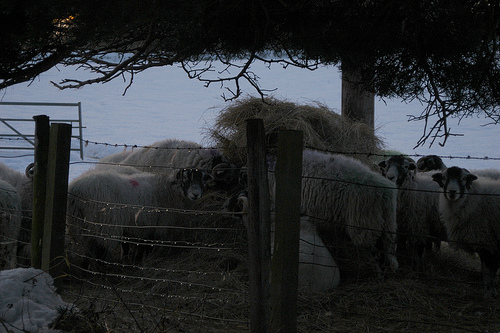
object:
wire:
[304, 143, 500, 163]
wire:
[300, 172, 500, 198]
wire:
[72, 190, 240, 219]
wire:
[74, 256, 249, 279]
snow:
[0, 52, 500, 182]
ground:
[2, 54, 500, 332]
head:
[375, 153, 420, 190]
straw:
[206, 94, 384, 168]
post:
[337, 47, 377, 137]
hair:
[258, 128, 290, 165]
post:
[244, 116, 275, 332]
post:
[265, 127, 303, 332]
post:
[28, 112, 50, 269]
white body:
[68, 171, 176, 258]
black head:
[167, 165, 213, 202]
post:
[41, 121, 75, 278]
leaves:
[483, 1, 498, 12]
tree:
[0, 0, 498, 155]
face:
[181, 168, 208, 200]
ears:
[428, 172, 447, 185]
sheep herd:
[1, 138, 498, 332]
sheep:
[1, 178, 26, 270]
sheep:
[430, 165, 498, 287]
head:
[430, 164, 479, 203]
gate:
[0, 99, 86, 166]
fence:
[0, 113, 500, 332]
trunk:
[340, 57, 375, 133]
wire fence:
[38, 117, 268, 332]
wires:
[71, 135, 249, 152]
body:
[252, 149, 402, 279]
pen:
[0, 101, 500, 332]